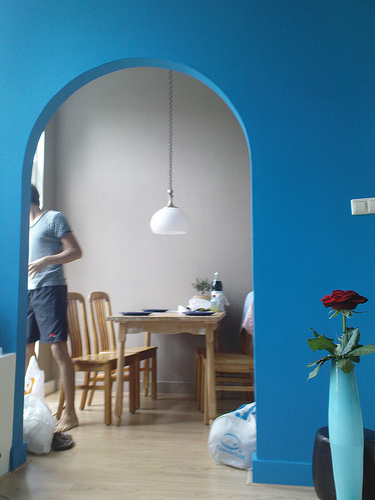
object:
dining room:
[21, 62, 262, 496]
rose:
[304, 289, 374, 386]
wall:
[3, 0, 374, 490]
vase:
[321, 344, 372, 500]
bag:
[207, 401, 256, 470]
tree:
[191, 275, 212, 295]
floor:
[0, 388, 319, 498]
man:
[26, 184, 83, 434]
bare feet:
[54, 413, 79, 433]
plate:
[114, 307, 155, 319]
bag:
[23, 354, 57, 454]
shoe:
[51, 429, 74, 450]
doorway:
[21, 53, 255, 484]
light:
[150, 201, 190, 235]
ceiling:
[119, 63, 209, 72]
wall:
[44, 68, 255, 394]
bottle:
[210, 271, 225, 311]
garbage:
[23, 372, 56, 455]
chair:
[88, 290, 158, 408]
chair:
[56, 291, 136, 426]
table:
[107, 306, 230, 425]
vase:
[326, 361, 366, 500]